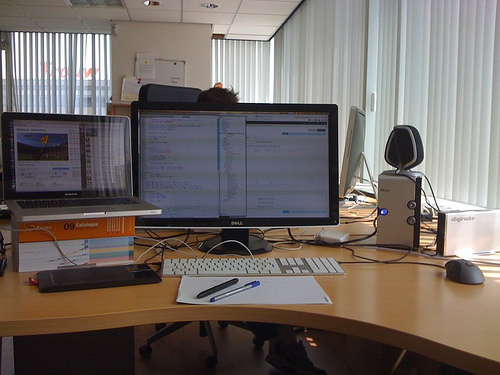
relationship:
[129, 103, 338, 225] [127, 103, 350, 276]
monitor of computer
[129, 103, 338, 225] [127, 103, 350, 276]
turned on monitor of computer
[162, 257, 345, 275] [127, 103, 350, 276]
keyboard of computer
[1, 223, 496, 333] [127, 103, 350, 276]
table under computer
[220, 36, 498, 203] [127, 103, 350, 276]
curtains behind computer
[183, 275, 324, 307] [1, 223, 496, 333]
paper on table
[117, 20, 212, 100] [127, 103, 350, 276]
wall behind computer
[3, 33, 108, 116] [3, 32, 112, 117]
blinds hanging on door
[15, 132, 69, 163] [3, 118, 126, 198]
video on monitor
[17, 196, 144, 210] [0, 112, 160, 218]
keyboard of laptop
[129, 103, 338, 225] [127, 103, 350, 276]
large monitor of computer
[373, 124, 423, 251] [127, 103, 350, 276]
computer speakers of computer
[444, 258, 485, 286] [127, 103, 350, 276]
mouse of computer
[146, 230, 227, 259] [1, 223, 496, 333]
wires on table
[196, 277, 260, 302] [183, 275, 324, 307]
an ink pen on paper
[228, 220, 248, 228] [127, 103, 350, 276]
dell logo on computer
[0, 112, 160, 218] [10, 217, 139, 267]
laptop on top of books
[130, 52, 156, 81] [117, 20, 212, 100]
papers on wall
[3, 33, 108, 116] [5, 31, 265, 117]
open blinds on wall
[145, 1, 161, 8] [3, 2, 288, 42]
bulb on ceiling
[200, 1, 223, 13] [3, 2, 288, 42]
bulb on ceiling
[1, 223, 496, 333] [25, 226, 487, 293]
computer desk with accessories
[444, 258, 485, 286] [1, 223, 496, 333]
computer mouse on table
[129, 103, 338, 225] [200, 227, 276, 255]
computer monitor on a stand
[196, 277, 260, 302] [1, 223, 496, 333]
an ink pen on desk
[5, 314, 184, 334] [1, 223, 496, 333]
edge of desk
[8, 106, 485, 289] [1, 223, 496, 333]
work station of desk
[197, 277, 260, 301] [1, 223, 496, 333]
pens on table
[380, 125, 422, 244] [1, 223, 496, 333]
computer speakers on table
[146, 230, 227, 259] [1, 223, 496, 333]
tangled cords on table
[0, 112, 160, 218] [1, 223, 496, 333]
small silver laptop on table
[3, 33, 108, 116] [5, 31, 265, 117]
white vertical blind on wall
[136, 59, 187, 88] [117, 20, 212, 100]
dry erase board on wall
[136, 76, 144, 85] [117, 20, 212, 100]
colorful thumb tacks on wall